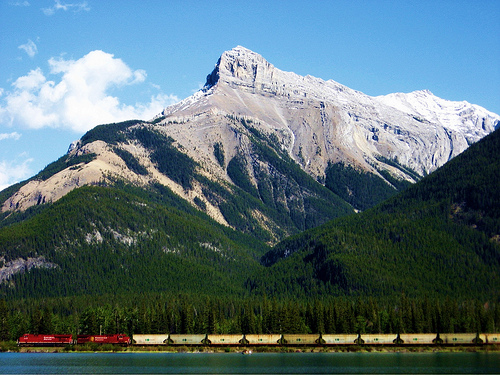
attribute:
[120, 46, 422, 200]
mountain — no trees 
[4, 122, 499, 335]
trees — green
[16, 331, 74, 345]
cars — two red train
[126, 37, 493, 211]
mountain —  tall gray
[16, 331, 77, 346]
train car — train 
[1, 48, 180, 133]
cloud — white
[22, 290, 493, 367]
train — Red 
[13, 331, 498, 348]
train — Red 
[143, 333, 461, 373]
water — turquoise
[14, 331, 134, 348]
red train — Red 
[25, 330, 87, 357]
red train — Red 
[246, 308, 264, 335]
tree — some 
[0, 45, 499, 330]
mountain — gray, parts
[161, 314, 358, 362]
cars — yellow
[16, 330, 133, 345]
train — Red 